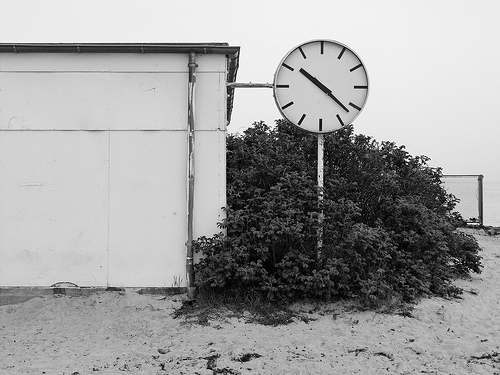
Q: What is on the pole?
A: A white clock.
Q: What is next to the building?
A: Bushes.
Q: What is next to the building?
A: A clock.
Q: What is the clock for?
A: Telling time.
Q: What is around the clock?
A: Bushes.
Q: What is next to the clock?
A: A building.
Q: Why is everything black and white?
A: An old picture.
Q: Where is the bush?
A: Around the clock.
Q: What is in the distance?
A: A building.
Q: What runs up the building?
A: A pipe.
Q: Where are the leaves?
A: On the ground.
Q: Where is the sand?
A: On a beach.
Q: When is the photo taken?
A: 10:22.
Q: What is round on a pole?
A: Face of clock.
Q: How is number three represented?
A: Horizontal line.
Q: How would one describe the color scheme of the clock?
A: Black and white.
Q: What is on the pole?
A: Clock.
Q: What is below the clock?
A: Bush.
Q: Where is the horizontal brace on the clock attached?
A: Building on left.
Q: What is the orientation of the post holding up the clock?
A: Vertical.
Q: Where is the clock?
A: In the bushes.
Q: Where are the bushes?
A: Sand.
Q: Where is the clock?
A: To the right of the building.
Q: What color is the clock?
A: White.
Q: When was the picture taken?
A: Daytime.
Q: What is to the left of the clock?
A: A building.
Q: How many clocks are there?
A: One.